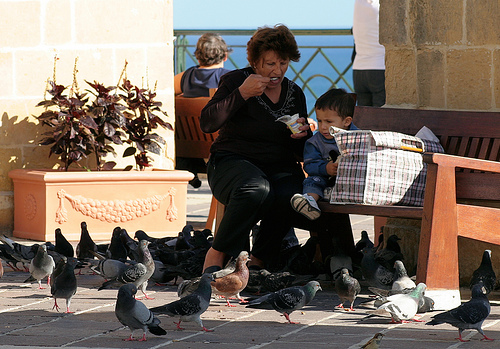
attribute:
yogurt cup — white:
[268, 108, 315, 144]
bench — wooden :
[214, 104, 499, 309]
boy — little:
[289, 86, 361, 221]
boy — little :
[289, 84, 387, 228]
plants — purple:
[33, 50, 175, 173]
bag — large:
[318, 113, 449, 204]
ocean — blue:
[304, 11, 352, 67]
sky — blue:
[173, 0, 356, 30]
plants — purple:
[83, 70, 130, 173]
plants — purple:
[123, 75, 173, 167]